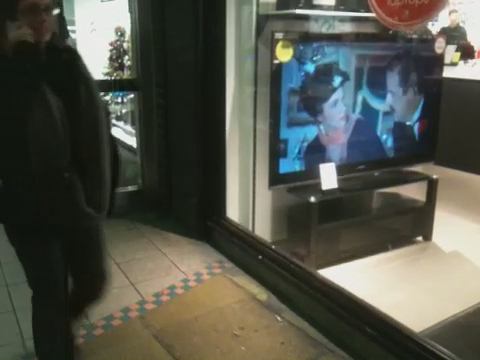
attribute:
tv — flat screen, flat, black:
[268, 30, 437, 179]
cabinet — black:
[292, 167, 443, 271]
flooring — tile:
[418, 226, 475, 325]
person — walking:
[2, 1, 138, 360]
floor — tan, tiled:
[424, 249, 480, 302]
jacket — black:
[2, 45, 116, 228]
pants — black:
[3, 217, 110, 359]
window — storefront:
[65, 6, 154, 183]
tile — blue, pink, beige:
[78, 253, 245, 344]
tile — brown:
[132, 235, 180, 271]